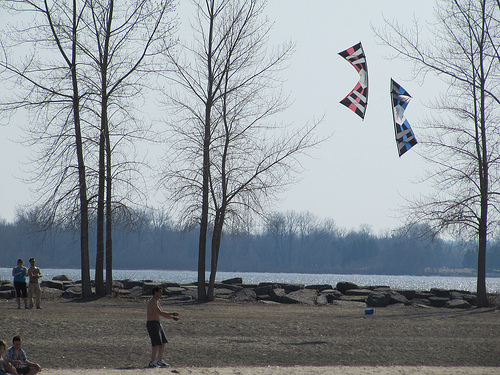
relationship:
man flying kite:
[144, 285, 182, 368] [333, 37, 373, 122]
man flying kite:
[144, 285, 182, 368] [384, 74, 420, 159]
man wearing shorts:
[141, 281, 168, 368] [145, 322, 168, 346]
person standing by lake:
[10, 258, 29, 313] [1, 266, 498, 293]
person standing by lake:
[25, 257, 44, 309] [1, 266, 498, 293]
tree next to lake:
[152, 0, 333, 302] [1, 266, 498, 293]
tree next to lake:
[0, 1, 182, 296] [1, 266, 498, 293]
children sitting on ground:
[0, 334, 40, 373] [0, 296, 498, 373]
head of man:
[147, 282, 164, 305] [143, 281, 176, 370]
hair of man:
[152, 285, 162, 292] [144, 286, 179, 368]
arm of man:
[162, 309, 212, 327] [132, 276, 239, 374]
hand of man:
[173, 312, 178, 316] [144, 286, 179, 368]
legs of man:
[150, 343, 165, 363] [144, 286, 179, 368]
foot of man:
[145, 356, 158, 370] [129, 286, 189, 354]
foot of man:
[156, 357, 171, 368] [129, 286, 189, 354]